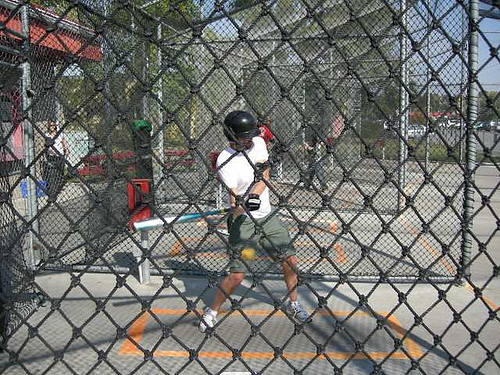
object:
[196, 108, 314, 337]
man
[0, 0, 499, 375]
cage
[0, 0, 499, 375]
black fence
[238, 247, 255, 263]
baseball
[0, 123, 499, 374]
field